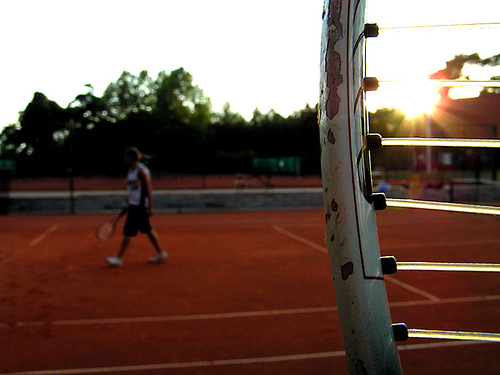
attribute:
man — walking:
[107, 147, 169, 268]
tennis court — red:
[0, 175, 499, 375]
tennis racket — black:
[96, 205, 128, 241]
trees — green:
[1, 56, 498, 173]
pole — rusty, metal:
[318, 0, 404, 374]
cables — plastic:
[364, 21, 499, 373]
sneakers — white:
[105, 251, 169, 265]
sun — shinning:
[397, 82, 441, 119]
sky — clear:
[1, 0, 499, 129]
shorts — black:
[122, 206, 153, 237]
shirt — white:
[125, 163, 152, 205]